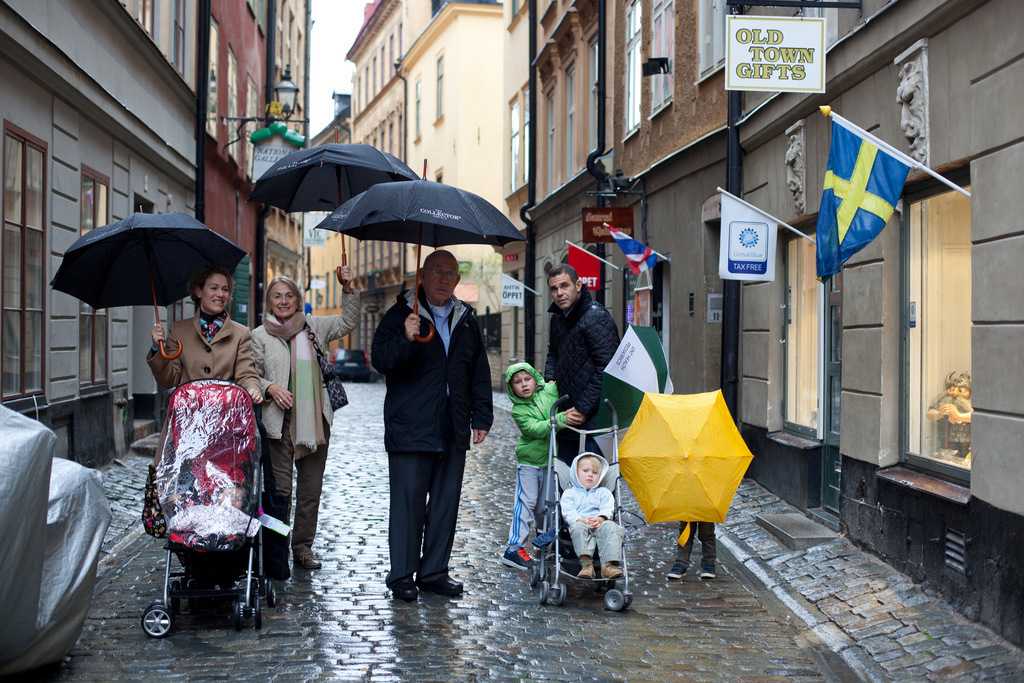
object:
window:
[876, 163, 972, 501]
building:
[720, 0, 1024, 654]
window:
[647, 0, 671, 121]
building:
[520, 0, 1024, 647]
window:
[79, 162, 112, 387]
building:
[0, 0, 312, 474]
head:
[417, 250, 461, 301]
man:
[370, 249, 493, 599]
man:
[544, 263, 623, 466]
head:
[547, 263, 583, 310]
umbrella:
[618, 388, 753, 524]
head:
[577, 456, 602, 489]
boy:
[559, 451, 624, 578]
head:
[187, 267, 234, 314]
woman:
[145, 266, 262, 405]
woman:
[250, 264, 359, 568]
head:
[266, 276, 302, 319]